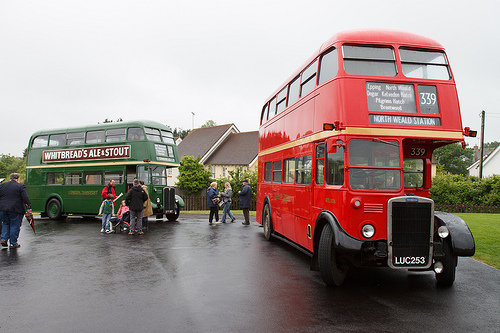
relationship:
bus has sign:
[255, 34, 477, 289] [366, 78, 412, 109]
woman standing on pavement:
[207, 179, 218, 222] [5, 212, 498, 333]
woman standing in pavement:
[221, 181, 233, 220] [5, 212, 498, 333]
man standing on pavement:
[238, 178, 253, 223] [5, 212, 498, 333]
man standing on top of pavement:
[126, 178, 147, 232] [5, 212, 498, 333]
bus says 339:
[255, 34, 477, 289] [419, 89, 436, 106]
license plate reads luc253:
[392, 252, 426, 267] [392, 254, 427, 263]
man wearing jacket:
[100, 178, 114, 234] [102, 187, 117, 202]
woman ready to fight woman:
[207, 179, 218, 222] [221, 181, 233, 220]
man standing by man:
[126, 178, 147, 232] [100, 178, 114, 234]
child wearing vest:
[101, 193, 113, 232] [102, 200, 112, 213]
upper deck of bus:
[255, 31, 461, 136] [255, 34, 477, 289]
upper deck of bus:
[22, 122, 180, 164] [26, 123, 178, 222]